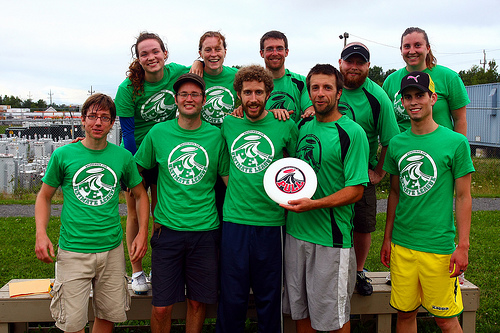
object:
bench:
[0, 271, 480, 332]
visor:
[337, 42, 400, 297]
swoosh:
[354, 47, 361, 50]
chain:
[0, 119, 121, 199]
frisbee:
[263, 157, 318, 205]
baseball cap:
[341, 42, 370, 63]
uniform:
[132, 118, 229, 307]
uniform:
[381, 124, 475, 320]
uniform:
[40, 140, 142, 332]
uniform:
[41, 62, 476, 333]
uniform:
[183, 64, 239, 128]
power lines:
[50, 94, 117, 107]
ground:
[0, 199, 28, 274]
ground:
[475, 168, 499, 286]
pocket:
[48, 279, 66, 324]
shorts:
[48, 240, 130, 332]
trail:
[0, 197, 499, 219]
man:
[34, 92, 149, 332]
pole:
[343, 32, 347, 47]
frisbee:
[231, 130, 275, 174]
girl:
[113, 30, 205, 296]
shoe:
[131, 271, 149, 295]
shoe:
[147, 270, 152, 281]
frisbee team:
[34, 27, 476, 333]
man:
[221, 64, 299, 333]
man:
[127, 73, 231, 333]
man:
[336, 42, 400, 297]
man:
[231, 30, 316, 118]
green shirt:
[382, 124, 476, 254]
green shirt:
[285, 115, 369, 249]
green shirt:
[221, 114, 300, 226]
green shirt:
[134, 117, 231, 231]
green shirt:
[40, 140, 143, 254]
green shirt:
[338, 77, 401, 170]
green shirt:
[265, 68, 314, 123]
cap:
[398, 71, 435, 95]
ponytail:
[125, 58, 144, 102]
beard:
[242, 100, 267, 119]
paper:
[8, 279, 50, 298]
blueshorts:
[150, 225, 218, 306]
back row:
[114, 27, 470, 154]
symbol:
[398, 150, 438, 197]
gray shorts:
[282, 233, 357, 331]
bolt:
[454, 277, 458, 302]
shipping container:
[465, 82, 499, 148]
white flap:
[133, 271, 148, 279]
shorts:
[388, 242, 464, 318]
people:
[34, 27, 476, 333]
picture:
[0, 0, 499, 333]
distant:
[0, 85, 95, 110]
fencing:
[0, 119, 85, 199]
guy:
[380, 71, 476, 333]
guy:
[282, 63, 371, 332]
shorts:
[285, 233, 358, 331]